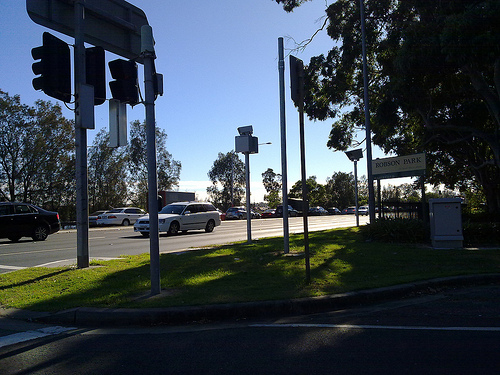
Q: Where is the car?
A: In the street.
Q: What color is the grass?
A: Green.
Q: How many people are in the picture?
A: None.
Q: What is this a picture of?
A: Traffic.